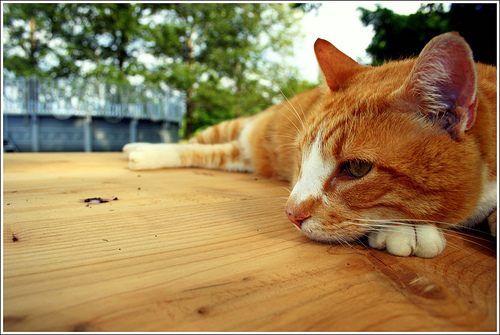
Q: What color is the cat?
A: Orange and white.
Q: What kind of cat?
A: Adult cat.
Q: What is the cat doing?
A: Laying down.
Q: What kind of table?
A: Wooden.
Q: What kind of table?
A: Picnic table.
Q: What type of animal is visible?
A: Cat.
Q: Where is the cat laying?
A: On wood.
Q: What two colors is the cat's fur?
A: Orange and white.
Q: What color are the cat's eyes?
A: Green.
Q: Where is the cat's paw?
A: Under its head.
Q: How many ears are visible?
A: 2.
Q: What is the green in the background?
A: Trees.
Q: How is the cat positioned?
A: Laying down.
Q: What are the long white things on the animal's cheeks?
A: Whiskers.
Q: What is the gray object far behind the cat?
A: Building.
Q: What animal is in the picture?
A: Cat.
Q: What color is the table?
A: Brown.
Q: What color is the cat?
A: Orange and white.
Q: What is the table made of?
A: Wood.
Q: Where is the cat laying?
A: On table.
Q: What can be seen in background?
A: Trees.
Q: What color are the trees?
A: Green.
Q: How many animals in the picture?
A: One.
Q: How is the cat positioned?
A: Laying down.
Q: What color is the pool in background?
A: Blue.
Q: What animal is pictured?
A: Cat.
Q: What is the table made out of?
A: Wood.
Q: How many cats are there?
A: 1.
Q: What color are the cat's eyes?
A: Green.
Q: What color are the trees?
A: Green.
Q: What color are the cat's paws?
A: White.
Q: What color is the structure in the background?
A: Blue.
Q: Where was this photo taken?
A: In the backyard.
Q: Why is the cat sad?
A: He is hungry.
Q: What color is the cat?
A: Orange and white.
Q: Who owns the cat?
A: A nun.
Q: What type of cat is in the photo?
A: A tabby.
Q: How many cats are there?
A: One.